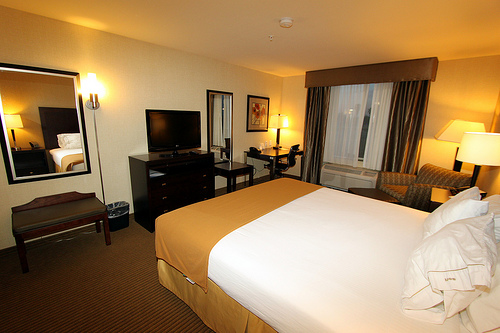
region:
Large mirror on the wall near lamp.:
[0, 53, 96, 182]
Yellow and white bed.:
[148, 175, 490, 332]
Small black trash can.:
[104, 198, 137, 233]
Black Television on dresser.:
[142, 105, 205, 156]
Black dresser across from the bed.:
[129, 150, 220, 230]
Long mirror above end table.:
[205, 87, 236, 163]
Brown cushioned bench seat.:
[7, 183, 114, 263]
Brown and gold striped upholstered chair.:
[375, 159, 477, 206]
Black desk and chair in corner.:
[245, 138, 304, 173]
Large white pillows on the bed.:
[409, 186, 497, 330]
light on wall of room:
[79, 67, 106, 114]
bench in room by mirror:
[6, 187, 112, 274]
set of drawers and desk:
[127, 149, 214, 231]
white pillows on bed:
[403, 186, 498, 325]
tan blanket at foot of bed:
[145, 177, 326, 292]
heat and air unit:
[318, 157, 379, 192]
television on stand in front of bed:
[141, 102, 206, 157]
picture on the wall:
[245, 88, 273, 134]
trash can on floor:
[103, 195, 135, 230]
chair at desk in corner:
[270, 141, 302, 176]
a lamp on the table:
[265, 110, 296, 167]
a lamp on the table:
[445, 111, 475, 193]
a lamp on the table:
[443, 121, 493, 211]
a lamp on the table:
[256, 108, 311, 158]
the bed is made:
[191, 170, 461, 331]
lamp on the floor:
[456, 133, 493, 190]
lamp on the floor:
[439, 110, 468, 165]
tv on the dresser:
[139, 107, 201, 152]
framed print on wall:
[243, 90, 270, 134]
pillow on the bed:
[418, 212, 495, 302]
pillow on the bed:
[423, 188, 478, 219]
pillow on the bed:
[467, 295, 499, 329]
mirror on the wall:
[1, 66, 96, 179]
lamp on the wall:
[81, 70, 111, 124]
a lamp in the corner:
[267, 111, 286, 157]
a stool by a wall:
[11, 190, 111, 277]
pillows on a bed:
[396, 182, 498, 320]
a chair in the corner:
[378, 163, 470, 205]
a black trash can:
[109, 199, 127, 237]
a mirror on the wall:
[204, 89, 237, 166]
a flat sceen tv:
[146, 106, 203, 156]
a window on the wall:
[324, 82, 406, 161]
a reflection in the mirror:
[6, 81, 84, 179]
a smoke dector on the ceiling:
[274, 16, 294, 31]